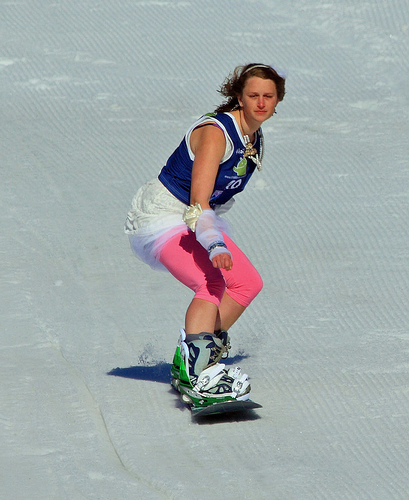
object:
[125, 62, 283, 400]
woman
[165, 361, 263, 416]
snowboard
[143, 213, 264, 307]
leggings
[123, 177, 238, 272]
skirt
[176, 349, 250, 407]
bindings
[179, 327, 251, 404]
boot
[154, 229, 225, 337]
leg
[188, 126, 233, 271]
arm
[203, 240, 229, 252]
bracelet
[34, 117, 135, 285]
tracks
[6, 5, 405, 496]
snow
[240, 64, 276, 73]
headband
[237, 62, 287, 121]
head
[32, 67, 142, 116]
foot prints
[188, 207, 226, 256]
white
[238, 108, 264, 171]
necklace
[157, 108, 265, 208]
shirt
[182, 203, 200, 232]
bow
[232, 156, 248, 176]
character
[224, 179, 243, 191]
number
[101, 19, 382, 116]
lines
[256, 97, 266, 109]
nose